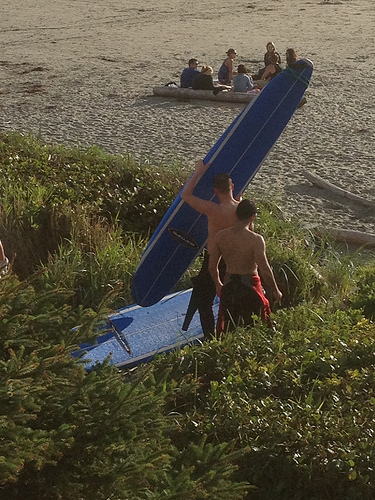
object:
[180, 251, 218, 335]
suits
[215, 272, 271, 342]
suits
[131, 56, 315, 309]
blue surfboard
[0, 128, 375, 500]
grass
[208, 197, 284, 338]
man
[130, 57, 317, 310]
surfboard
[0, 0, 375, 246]
beach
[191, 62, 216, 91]
woman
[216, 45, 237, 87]
woman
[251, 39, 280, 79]
woman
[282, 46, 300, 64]
woman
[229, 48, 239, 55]
sunglasses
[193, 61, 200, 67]
sunglasses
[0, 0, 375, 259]
sand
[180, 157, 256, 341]
man